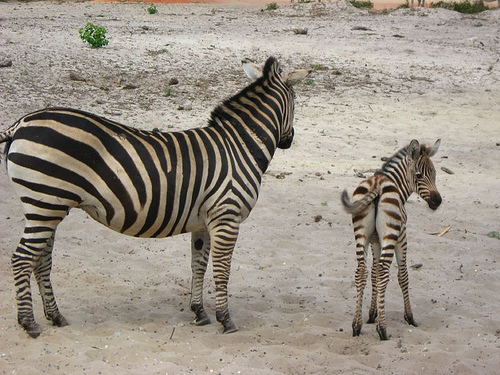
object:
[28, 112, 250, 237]
stripes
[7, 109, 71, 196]
rump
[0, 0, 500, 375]
ground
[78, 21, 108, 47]
plant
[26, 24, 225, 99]
sand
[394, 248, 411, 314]
leg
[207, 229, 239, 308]
leg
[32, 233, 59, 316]
leg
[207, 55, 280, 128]
mane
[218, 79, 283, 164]
neck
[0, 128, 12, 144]
tail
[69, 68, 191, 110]
rocks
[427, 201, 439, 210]
mouth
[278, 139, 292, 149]
mouth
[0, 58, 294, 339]
zebra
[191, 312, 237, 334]
feet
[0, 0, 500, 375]
grey sand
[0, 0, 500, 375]
sandy area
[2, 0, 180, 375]
left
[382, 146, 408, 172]
mane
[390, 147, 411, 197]
neck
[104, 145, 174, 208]
strips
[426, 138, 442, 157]
ear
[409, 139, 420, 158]
ear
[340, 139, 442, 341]
young zebra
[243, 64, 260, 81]
ear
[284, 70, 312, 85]
ear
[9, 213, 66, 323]
legs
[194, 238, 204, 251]
spot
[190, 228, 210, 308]
leg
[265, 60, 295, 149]
head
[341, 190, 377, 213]
tail